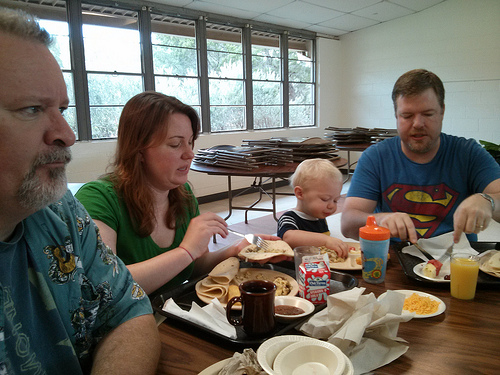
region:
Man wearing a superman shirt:
[341, 72, 477, 242]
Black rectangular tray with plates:
[146, 250, 367, 347]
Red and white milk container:
[294, 254, 349, 304]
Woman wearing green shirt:
[62, 80, 274, 309]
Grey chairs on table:
[189, 95, 366, 214]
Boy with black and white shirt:
[288, 152, 365, 266]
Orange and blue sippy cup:
[357, 218, 405, 301]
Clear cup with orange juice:
[442, 240, 485, 307]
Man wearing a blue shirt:
[10, 55, 160, 369]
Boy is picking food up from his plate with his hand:
[270, 150, 362, 273]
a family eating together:
[0, 14, 498, 373]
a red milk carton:
[277, 238, 364, 338]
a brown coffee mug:
[211, 265, 306, 353]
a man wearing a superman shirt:
[337, 67, 499, 242]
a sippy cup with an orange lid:
[344, 207, 408, 301]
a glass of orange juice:
[440, 244, 494, 327]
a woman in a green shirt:
[86, 79, 231, 289]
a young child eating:
[257, 134, 402, 311]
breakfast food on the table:
[138, 172, 498, 364]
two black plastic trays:
[147, 225, 498, 345]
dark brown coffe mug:
[230, 275, 280, 339]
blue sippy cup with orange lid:
[355, 206, 400, 292]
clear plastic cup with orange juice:
[443, 246, 489, 303]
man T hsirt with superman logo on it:
[353, 123, 497, 248]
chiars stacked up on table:
[207, 126, 276, 188]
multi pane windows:
[187, 13, 365, 159]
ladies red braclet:
[168, 223, 216, 277]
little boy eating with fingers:
[277, 143, 396, 295]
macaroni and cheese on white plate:
[390, 284, 454, 319]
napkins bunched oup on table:
[315, 283, 406, 373]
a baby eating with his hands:
[270, 140, 373, 270]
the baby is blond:
[272, 145, 360, 276]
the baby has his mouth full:
[273, 138, 369, 269]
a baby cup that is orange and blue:
[350, 214, 395, 289]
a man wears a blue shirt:
[337, 59, 499, 268]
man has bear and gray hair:
[1, 9, 163, 371]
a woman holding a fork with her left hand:
[88, 78, 304, 333]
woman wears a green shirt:
[67, 82, 287, 324]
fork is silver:
[224, 221, 274, 255]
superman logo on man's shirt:
[364, 172, 488, 255]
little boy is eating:
[269, 147, 354, 269]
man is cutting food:
[338, 68, 496, 290]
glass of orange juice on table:
[435, 236, 495, 318]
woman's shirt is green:
[70, 157, 203, 297]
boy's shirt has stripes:
[264, 199, 303, 239]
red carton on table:
[293, 241, 339, 316]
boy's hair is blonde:
[273, 145, 344, 199]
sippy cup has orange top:
[353, 203, 395, 290]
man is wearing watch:
[463, 184, 498, 213]